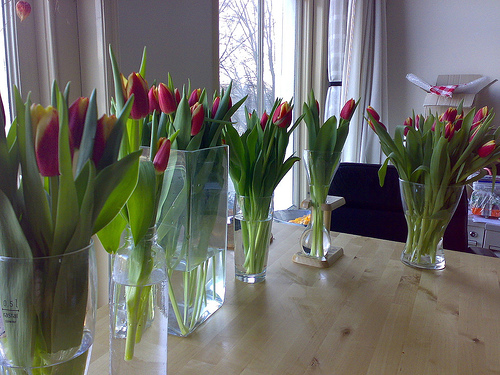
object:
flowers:
[152, 135, 172, 174]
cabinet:
[464, 219, 484, 250]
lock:
[466, 230, 479, 239]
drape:
[324, 0, 392, 165]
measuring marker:
[0, 296, 21, 324]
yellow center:
[28, 101, 55, 153]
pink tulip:
[189, 99, 205, 138]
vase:
[0, 238, 102, 374]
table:
[87, 214, 500, 374]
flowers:
[476, 138, 498, 160]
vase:
[396, 177, 466, 272]